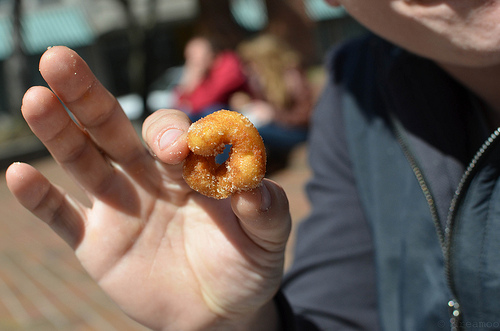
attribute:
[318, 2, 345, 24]
ear —  person's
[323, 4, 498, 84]
face —  shadowed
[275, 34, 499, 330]
jacket — dark blue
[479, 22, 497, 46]
chin —  man's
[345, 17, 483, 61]
jaw —  man's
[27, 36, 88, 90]
finger —  with sugar